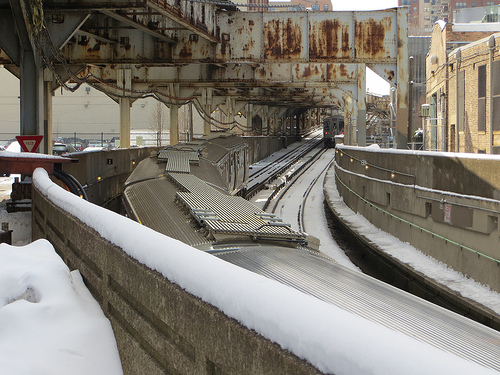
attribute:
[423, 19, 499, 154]
building — part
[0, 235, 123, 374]
snow — part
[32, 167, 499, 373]
wall — part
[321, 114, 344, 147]
train — part, going, passing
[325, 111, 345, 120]
top — gray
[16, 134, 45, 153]
sign — yeild, red, white, black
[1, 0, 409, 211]
overpass — steel, rusted, metal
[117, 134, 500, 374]
train — gray, silver, passing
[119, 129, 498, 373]
top — gray